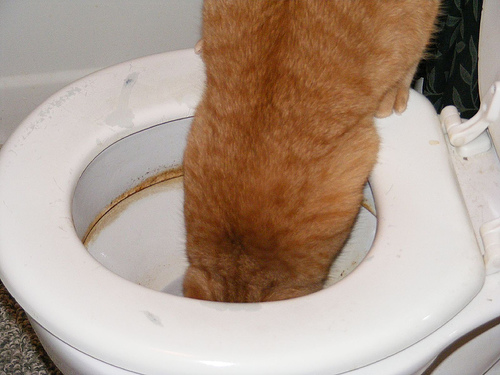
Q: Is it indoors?
A: Yes, it is indoors.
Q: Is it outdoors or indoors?
A: It is indoors.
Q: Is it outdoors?
A: No, it is indoors.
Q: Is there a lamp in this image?
A: No, there are no lamps.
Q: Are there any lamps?
A: No, there are no lamps.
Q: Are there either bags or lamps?
A: No, there are no lamps or bags.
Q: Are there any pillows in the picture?
A: No, there are no pillows.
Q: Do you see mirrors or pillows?
A: No, there are no pillows or mirrors.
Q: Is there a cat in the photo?
A: Yes, there is a cat.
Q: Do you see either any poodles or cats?
A: Yes, there is a cat.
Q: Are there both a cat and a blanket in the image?
A: No, there is a cat but no blankets.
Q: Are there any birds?
A: No, there are no birds.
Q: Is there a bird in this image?
A: No, there are no birds.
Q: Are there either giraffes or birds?
A: No, there are no birds or giraffes.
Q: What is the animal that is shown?
A: The animal is a cat.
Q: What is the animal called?
A: The animal is a cat.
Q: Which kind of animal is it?
A: The animal is a cat.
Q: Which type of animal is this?
A: This is a cat.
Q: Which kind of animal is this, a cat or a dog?
A: This is a cat.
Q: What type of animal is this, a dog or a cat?
A: This is a cat.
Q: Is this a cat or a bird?
A: This is a cat.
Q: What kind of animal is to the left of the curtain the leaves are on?
A: The animal is a cat.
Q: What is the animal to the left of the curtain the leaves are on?
A: The animal is a cat.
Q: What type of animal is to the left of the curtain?
A: The animal is a cat.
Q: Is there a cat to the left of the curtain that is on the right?
A: Yes, there is a cat to the left of the curtain.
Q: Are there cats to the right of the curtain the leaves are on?
A: No, the cat is to the left of the curtain.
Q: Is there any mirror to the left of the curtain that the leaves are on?
A: No, there is a cat to the left of the curtain.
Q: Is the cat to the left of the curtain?
A: Yes, the cat is to the left of the curtain.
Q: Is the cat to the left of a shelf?
A: No, the cat is to the left of the curtain.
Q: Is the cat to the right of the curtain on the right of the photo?
A: No, the cat is to the left of the curtain.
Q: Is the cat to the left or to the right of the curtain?
A: The cat is to the left of the curtain.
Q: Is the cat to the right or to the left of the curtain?
A: The cat is to the left of the curtain.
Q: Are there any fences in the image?
A: No, there are no fences.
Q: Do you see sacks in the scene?
A: No, there are no sacks.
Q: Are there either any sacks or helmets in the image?
A: No, there are no sacks or helmets.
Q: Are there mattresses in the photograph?
A: No, there are no mattresses.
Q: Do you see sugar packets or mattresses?
A: No, there are no mattresses or sugar packets.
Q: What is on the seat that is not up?
A: The dirt is on the seat.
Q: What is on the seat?
A: The dirt is on the seat.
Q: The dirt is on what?
A: The dirt is on the seat.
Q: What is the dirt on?
A: The dirt is on the seat.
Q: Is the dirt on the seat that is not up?
A: Yes, the dirt is on the seat.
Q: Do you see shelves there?
A: No, there are no shelves.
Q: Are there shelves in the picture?
A: No, there are no shelves.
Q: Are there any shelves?
A: No, there are no shelves.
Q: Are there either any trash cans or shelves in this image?
A: No, there are no shelves or trash cans.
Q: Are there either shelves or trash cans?
A: No, there are no shelves or trash cans.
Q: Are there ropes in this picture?
A: No, there are no ropes.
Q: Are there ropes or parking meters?
A: No, there are no ropes or parking meters.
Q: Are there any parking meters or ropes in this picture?
A: No, there are no ropes or parking meters.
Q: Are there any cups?
A: No, there are no cups.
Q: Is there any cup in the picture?
A: No, there are no cups.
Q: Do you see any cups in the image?
A: No, there are no cups.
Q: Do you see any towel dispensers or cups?
A: No, there are no cups or towel dispensers.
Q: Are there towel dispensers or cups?
A: No, there are no cups or towel dispensers.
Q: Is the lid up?
A: Yes, the lid is up.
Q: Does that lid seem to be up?
A: Yes, the lid is up.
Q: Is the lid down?
A: No, the lid is up.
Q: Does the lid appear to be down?
A: No, the lid is up.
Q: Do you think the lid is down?
A: No, the lid is up.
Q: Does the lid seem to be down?
A: No, the lid is up.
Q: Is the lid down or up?
A: The lid is up.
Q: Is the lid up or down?
A: The lid is up.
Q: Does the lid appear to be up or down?
A: The lid is up.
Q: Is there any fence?
A: No, there are no fences.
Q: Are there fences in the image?
A: No, there are no fences.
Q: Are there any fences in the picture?
A: No, there are no fences.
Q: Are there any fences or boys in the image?
A: No, there are no fences or boys.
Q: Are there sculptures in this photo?
A: No, there are no sculptures.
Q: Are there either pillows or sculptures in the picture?
A: No, there are no sculptures or pillows.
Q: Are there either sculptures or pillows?
A: No, there are no sculptures or pillows.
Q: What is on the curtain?
A: The leaves are on the curtain.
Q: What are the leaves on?
A: The leaves are on the curtain.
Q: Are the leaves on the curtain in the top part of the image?
A: Yes, the leaves are on the curtain.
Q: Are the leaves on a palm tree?
A: No, the leaves are on the curtain.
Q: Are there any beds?
A: No, there are no beds.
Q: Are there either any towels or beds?
A: No, there are no beds or towels.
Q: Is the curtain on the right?
A: Yes, the curtain is on the right of the image.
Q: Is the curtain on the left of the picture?
A: No, the curtain is on the right of the image.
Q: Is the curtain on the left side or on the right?
A: The curtain is on the right of the image.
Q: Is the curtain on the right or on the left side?
A: The curtain is on the right of the image.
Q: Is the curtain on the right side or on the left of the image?
A: The curtain is on the right of the image.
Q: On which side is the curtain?
A: The curtain is on the right of the image.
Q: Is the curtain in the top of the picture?
A: Yes, the curtain is in the top of the image.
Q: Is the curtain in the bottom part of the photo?
A: No, the curtain is in the top of the image.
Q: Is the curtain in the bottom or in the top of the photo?
A: The curtain is in the top of the image.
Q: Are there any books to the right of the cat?
A: No, there is a curtain to the right of the cat.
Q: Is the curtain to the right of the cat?
A: Yes, the curtain is to the right of the cat.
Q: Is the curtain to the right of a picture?
A: No, the curtain is to the right of the cat.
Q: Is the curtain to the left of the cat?
A: No, the curtain is to the right of the cat.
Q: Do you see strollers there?
A: No, there are no strollers.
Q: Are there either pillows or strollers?
A: No, there are no strollers or pillows.